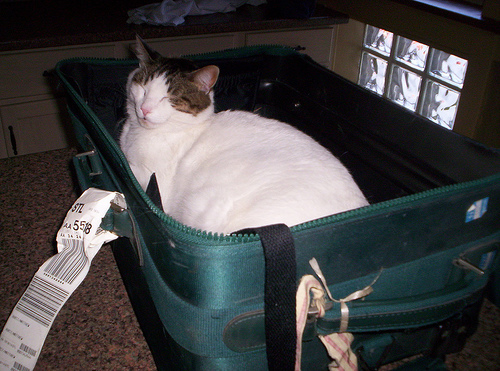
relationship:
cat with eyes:
[115, 27, 370, 248] [131, 76, 179, 111]